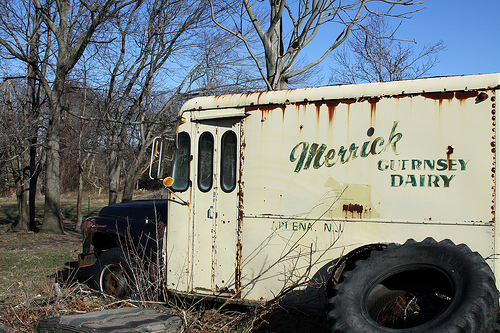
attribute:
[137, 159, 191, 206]
reflector — Orange 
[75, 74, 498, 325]
dairy truck — old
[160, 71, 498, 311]
delivery truck — Old 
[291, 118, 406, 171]
lettering — green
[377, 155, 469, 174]
lettering — green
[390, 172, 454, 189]
lettering — green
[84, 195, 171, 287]
paint — black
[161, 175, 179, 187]
reflector — orange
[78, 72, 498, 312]
truck — old, black, antique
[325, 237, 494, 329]
tire — large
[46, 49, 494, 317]
truck — old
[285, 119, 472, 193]
writing — green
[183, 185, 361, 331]
branches — Dead 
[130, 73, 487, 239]
dairy truck — old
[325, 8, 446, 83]
branches — long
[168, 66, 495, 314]
truck — antique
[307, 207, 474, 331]
tire — bigblue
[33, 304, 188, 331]
rock — grey , large 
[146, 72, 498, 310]
truck — old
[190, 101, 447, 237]
truck — Green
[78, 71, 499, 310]
milk truck — rrusted